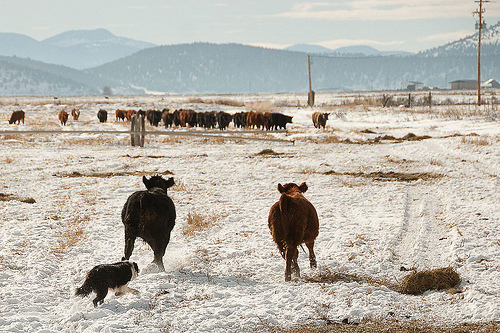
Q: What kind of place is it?
A: It is a pasture.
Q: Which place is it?
A: It is a pasture.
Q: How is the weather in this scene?
A: It is cloudy.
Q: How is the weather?
A: It is cloudy.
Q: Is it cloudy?
A: Yes, it is cloudy.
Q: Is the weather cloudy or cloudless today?
A: It is cloudy.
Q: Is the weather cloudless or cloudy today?
A: It is cloudy.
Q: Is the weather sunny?
A: No, it is cloudy.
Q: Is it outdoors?
A: Yes, it is outdoors.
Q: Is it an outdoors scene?
A: Yes, it is outdoors.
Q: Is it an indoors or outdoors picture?
A: It is outdoors.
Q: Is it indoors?
A: No, it is outdoors.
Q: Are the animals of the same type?
A: No, there are both dogs and cows.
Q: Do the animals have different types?
A: Yes, they are dogs and cows.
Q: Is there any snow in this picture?
A: Yes, there is snow.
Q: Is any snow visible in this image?
A: Yes, there is snow.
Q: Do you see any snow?
A: Yes, there is snow.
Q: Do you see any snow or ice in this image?
A: Yes, there is snow.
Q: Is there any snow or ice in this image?
A: Yes, there is snow.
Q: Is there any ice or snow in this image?
A: Yes, there is snow.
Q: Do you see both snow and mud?
A: No, there is snow but no mud.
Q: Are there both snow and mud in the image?
A: No, there is snow but no mud.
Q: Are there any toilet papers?
A: No, there are no toilet papers.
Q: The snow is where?
A: The snow is on the pasture.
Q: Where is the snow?
A: The snow is on the pasture.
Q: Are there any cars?
A: No, there are no cars.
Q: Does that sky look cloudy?
A: Yes, the sky is cloudy.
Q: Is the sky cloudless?
A: No, the sky is cloudy.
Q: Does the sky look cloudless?
A: No, the sky is cloudy.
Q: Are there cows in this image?
A: Yes, there is a cow.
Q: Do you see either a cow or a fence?
A: Yes, there is a cow.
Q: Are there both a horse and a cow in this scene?
A: No, there is a cow but no horses.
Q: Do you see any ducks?
A: No, there are no ducks.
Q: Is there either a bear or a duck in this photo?
A: No, there are no ducks or bears.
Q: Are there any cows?
A: Yes, there is a cow.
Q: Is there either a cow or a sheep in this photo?
A: Yes, there is a cow.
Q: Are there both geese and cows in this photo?
A: No, there is a cow but no geese.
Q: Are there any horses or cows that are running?
A: Yes, the cow is running.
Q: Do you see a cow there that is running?
A: Yes, there is a cow that is running.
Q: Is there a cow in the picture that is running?
A: Yes, there is a cow that is running.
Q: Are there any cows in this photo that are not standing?
A: Yes, there is a cow that is running.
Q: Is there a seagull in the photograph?
A: No, there are no seagulls.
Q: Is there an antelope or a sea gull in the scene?
A: No, there are no seagulls or antelopes.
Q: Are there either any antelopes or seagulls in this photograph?
A: No, there are no seagulls or antelopes.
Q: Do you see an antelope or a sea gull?
A: No, there are no seagulls or antelopes.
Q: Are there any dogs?
A: Yes, there is a dog.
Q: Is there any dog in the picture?
A: Yes, there is a dog.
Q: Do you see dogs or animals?
A: Yes, there is a dog.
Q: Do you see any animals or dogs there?
A: Yes, there is a dog.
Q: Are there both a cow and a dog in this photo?
A: Yes, there are both a dog and a cow.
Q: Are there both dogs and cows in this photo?
A: Yes, there are both a dog and a cow.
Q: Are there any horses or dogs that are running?
A: Yes, the dog is running.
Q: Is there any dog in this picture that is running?
A: Yes, there is a dog that is running.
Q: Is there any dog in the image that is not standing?
A: Yes, there is a dog that is running.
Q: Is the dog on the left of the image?
A: Yes, the dog is on the left of the image.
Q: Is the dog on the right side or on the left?
A: The dog is on the left of the image.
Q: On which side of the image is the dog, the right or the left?
A: The dog is on the left of the image.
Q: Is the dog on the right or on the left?
A: The dog is on the left of the image.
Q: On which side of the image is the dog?
A: The dog is on the left of the image.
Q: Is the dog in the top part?
A: No, the dog is in the bottom of the image.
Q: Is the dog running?
A: Yes, the dog is running.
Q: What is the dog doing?
A: The dog is running.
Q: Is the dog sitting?
A: No, the dog is running.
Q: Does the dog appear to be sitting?
A: No, the dog is running.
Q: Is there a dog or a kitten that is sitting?
A: No, there is a dog but it is running.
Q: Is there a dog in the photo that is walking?
A: No, there is a dog but it is running.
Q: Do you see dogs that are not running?
A: No, there is a dog but it is running.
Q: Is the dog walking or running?
A: The dog is running.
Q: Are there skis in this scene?
A: No, there are no skis.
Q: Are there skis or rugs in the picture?
A: No, there are no skis or rugs.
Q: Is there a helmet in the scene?
A: No, there are no helmets.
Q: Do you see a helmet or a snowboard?
A: No, there are no helmets or snowboards.